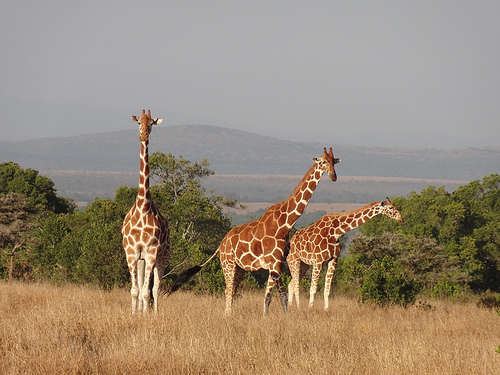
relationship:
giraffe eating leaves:
[281, 195, 403, 317] [338, 172, 498, 307]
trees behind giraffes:
[349, 157, 499, 335] [118, 105, 405, 318]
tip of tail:
[162, 267, 201, 292] [164, 244, 221, 300]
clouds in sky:
[62, 8, 142, 48] [5, 7, 497, 107]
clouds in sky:
[12, 80, 82, 100] [2, 0, 499, 239]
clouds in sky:
[44, 92, 99, 128] [2, 1, 499, 136]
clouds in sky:
[228, 54, 316, 95] [5, 7, 497, 107]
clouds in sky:
[170, 96, 243, 122] [15, 17, 482, 99]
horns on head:
[136, 111, 156, 119] [130, 105, 164, 144]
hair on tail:
[167, 264, 201, 293] [163, 246, 215, 297]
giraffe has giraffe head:
[281, 195, 403, 317] [377, 195, 405, 224]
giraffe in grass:
[117, 108, 170, 319] [0, 283, 498, 373]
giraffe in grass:
[162, 147, 340, 316] [0, 283, 498, 373]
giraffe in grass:
[281, 195, 403, 317] [0, 283, 498, 373]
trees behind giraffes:
[11, 147, 481, 296] [118, 105, 405, 318]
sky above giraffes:
[2, 1, 499, 136] [118, 105, 405, 318]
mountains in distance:
[7, 122, 496, 193] [0, 64, 484, 179]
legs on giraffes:
[122, 256, 339, 318] [81, 95, 402, 329]